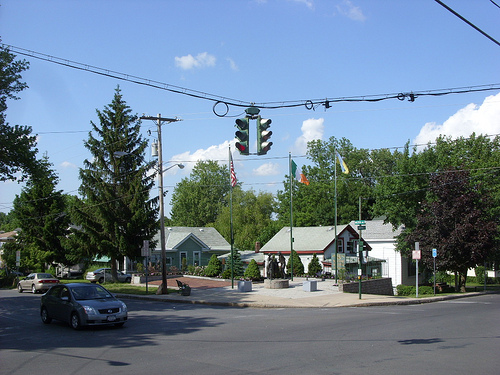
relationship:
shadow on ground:
[4, 292, 228, 349] [3, 288, 483, 373]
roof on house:
[150, 225, 242, 253] [135, 222, 262, 283]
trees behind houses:
[174, 117, 484, 214] [180, 156, 430, 310]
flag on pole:
[284, 150, 310, 185] [287, 190, 297, 248]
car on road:
[15, 270, 65, 295] [0, 291, 500, 373]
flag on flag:
[218, 150, 243, 192] [230, 151, 237, 187]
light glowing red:
[219, 141, 244, 216] [233, 140, 245, 151]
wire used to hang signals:
[12, 42, 499, 132] [231, 114, 271, 154]